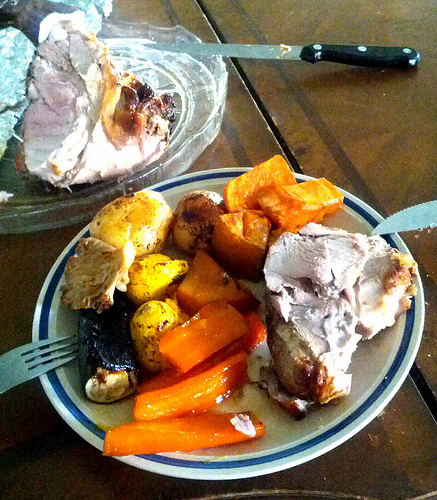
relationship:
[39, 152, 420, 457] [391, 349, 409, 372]
dish has border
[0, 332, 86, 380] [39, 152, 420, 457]
fork on dish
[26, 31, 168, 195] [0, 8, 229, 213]
meat on container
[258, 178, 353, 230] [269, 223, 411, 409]
sweet potato next to meat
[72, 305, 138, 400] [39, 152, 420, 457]
zucchini on dish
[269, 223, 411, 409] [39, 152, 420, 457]
meat on dish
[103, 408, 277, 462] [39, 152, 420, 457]
carrot on dish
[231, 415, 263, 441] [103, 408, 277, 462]
meat on carrot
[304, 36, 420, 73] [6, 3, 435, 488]
knife handle on table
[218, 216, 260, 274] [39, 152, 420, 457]
sweet potato on dish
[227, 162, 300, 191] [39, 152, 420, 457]
sweet potato on dish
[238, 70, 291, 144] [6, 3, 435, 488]
gap in table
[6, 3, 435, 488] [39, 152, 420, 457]
table under dish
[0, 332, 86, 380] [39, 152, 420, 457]
fork next to dish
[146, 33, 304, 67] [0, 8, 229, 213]
knife blade on container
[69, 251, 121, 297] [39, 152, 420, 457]
food on dish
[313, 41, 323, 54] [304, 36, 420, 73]
circle on knife handle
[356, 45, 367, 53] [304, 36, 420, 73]
circle on knife handle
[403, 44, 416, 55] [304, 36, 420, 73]
circle on knife handle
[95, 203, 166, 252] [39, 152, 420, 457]
food on dish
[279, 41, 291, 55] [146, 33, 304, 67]
food on knife blade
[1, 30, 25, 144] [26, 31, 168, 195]
foil next to meat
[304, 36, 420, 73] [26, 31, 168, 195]
knife handle next to meat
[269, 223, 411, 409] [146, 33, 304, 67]
meat on knife blade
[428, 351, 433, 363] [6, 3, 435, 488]
crumb on table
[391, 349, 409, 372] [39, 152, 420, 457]
border around dish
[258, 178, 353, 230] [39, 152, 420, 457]
sweet potato on dish